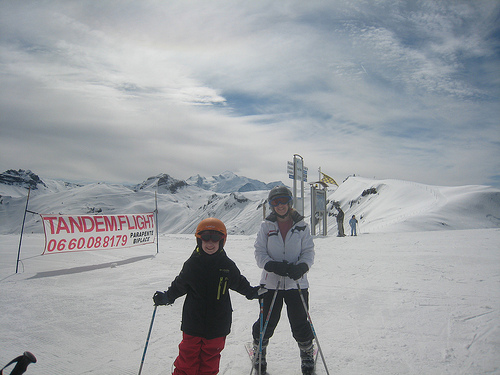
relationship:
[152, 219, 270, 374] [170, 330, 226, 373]
kid wearing pants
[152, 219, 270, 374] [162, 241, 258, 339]
kid wearing coat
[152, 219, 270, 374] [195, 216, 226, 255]
kid wearing helmet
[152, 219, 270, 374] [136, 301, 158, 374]
kid holding ski pole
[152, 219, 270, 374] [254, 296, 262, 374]
kid holding ski pole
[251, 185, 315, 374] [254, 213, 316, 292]
man wearing coat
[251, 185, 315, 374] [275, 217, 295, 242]
man wearing shirt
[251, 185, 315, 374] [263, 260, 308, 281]
man wearing gloves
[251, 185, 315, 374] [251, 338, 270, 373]
man wearing ski boot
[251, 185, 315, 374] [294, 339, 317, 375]
man wearing ski boot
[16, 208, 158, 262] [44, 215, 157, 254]
banner has writing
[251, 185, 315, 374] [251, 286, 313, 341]
man wearing pants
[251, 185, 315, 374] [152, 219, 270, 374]
man behind kid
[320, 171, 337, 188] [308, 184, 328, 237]
flag above sign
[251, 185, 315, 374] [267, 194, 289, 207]
man wearing goggles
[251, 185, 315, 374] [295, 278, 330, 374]
man holding ski pole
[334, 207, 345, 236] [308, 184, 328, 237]
person next to sign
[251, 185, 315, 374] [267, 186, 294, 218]
man wearing helmet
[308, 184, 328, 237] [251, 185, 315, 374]
sign behind man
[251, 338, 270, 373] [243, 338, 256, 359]
ski boot on ski